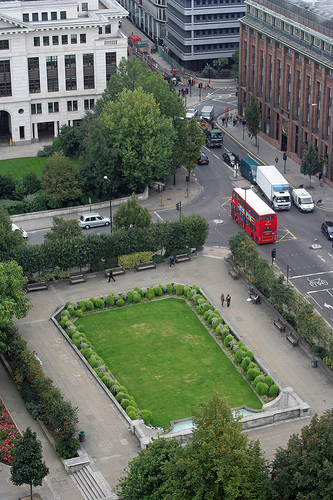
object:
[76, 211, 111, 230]
car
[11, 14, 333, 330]
street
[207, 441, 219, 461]
leaves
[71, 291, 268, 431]
grass area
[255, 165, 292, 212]
commercial truck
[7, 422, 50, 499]
tree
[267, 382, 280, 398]
bush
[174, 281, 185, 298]
bush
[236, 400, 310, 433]
wall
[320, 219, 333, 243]
car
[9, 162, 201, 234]
sidewalk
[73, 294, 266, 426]
grass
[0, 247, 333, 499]
park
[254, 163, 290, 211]
truck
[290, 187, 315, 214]
van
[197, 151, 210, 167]
car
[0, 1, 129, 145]
building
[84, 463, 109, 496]
steps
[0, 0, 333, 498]
urban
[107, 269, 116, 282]
pedestrian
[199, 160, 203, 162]
stoplight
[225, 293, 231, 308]
person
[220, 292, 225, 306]
person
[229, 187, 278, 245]
bus